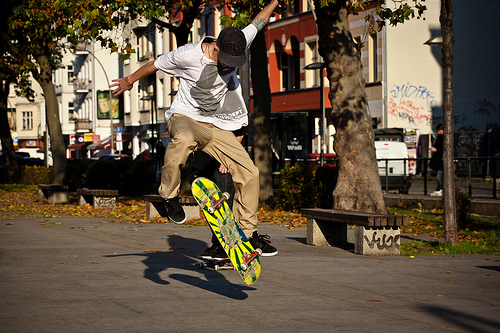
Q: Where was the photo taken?
A: It was taken at the park.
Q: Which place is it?
A: It is a park.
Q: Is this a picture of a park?
A: Yes, it is showing a park.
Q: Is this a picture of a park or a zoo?
A: It is showing a park.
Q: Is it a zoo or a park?
A: It is a park.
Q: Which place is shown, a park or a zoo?
A: It is a park.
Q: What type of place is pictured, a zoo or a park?
A: It is a park.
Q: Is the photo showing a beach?
A: No, the picture is showing a park.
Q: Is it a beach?
A: No, it is a park.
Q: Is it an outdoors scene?
A: Yes, it is outdoors.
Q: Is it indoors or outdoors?
A: It is outdoors.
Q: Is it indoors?
A: No, it is outdoors.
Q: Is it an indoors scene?
A: No, it is outdoors.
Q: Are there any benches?
A: Yes, there is a bench.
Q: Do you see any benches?
A: Yes, there is a bench.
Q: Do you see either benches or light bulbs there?
A: Yes, there is a bench.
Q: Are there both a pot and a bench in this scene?
A: No, there is a bench but no pots.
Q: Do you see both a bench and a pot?
A: No, there is a bench but no pots.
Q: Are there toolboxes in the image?
A: No, there are no toolboxes.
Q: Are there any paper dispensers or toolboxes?
A: No, there are no toolboxes or paper dispensers.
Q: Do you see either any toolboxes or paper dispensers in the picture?
A: No, there are no toolboxes or paper dispensers.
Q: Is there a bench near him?
A: Yes, there is a bench near the boy.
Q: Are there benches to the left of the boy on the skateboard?
A: Yes, there is a bench to the left of the boy.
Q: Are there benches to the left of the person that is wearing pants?
A: Yes, there is a bench to the left of the boy.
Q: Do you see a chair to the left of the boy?
A: No, there is a bench to the left of the boy.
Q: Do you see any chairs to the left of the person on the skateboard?
A: No, there is a bench to the left of the boy.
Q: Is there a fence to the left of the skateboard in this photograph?
A: No, there is a bench to the left of the skateboard.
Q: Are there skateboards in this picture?
A: Yes, there is a skateboard.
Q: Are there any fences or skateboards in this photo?
A: Yes, there is a skateboard.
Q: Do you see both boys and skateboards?
A: Yes, there are both a skateboard and a boy.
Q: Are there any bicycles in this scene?
A: No, there are no bicycles.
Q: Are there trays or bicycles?
A: No, there are no bicycles or trays.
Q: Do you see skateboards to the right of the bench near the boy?
A: Yes, there is a skateboard to the right of the bench.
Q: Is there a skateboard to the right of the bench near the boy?
A: Yes, there is a skateboard to the right of the bench.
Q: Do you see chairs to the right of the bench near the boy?
A: No, there is a skateboard to the right of the bench.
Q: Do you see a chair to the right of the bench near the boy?
A: No, there is a skateboard to the right of the bench.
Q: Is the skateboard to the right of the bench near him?
A: Yes, the skateboard is to the right of the bench.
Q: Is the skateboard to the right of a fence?
A: No, the skateboard is to the right of the bench.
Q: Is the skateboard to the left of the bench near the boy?
A: No, the skateboard is to the right of the bench.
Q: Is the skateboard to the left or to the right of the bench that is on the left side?
A: The skateboard is to the right of the bench.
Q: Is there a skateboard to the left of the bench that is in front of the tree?
A: Yes, there is a skateboard to the left of the bench.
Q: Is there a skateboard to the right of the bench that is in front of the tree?
A: No, the skateboard is to the left of the bench.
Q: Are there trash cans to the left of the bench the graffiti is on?
A: No, there is a skateboard to the left of the bench.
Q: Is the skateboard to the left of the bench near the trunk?
A: Yes, the skateboard is to the left of the bench.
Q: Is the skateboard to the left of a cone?
A: No, the skateboard is to the left of the bench.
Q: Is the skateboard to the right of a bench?
A: No, the skateboard is to the left of a bench.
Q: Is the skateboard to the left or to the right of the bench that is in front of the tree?
A: The skateboard is to the left of the bench.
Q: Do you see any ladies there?
A: No, there are no ladies.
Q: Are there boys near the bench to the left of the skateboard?
A: Yes, there is a boy near the bench.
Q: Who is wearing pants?
A: The boy is wearing pants.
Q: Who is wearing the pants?
A: The boy is wearing pants.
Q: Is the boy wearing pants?
A: Yes, the boy is wearing pants.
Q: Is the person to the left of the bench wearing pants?
A: Yes, the boy is wearing pants.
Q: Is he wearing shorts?
A: No, the boy is wearing pants.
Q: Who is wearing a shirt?
A: The boy is wearing a shirt.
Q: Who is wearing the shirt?
A: The boy is wearing a shirt.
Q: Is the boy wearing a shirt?
A: Yes, the boy is wearing a shirt.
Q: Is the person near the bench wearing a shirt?
A: Yes, the boy is wearing a shirt.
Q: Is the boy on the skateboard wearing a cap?
A: No, the boy is wearing a shirt.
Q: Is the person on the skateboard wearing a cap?
A: No, the boy is wearing a shirt.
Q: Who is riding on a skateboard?
A: The boy is riding on a skateboard.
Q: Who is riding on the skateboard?
A: The boy is riding on a skateboard.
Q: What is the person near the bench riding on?
A: The boy is riding on a skateboard.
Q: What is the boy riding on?
A: The boy is riding on a skateboard.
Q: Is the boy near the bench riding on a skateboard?
A: Yes, the boy is riding on a skateboard.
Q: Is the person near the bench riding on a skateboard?
A: Yes, the boy is riding on a skateboard.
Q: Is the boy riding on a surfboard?
A: No, the boy is riding on a skateboard.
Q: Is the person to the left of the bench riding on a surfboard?
A: No, the boy is riding on a skateboard.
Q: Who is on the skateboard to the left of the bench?
A: The boy is on the skateboard.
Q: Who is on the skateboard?
A: The boy is on the skateboard.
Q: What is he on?
A: The boy is on the skateboard.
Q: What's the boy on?
A: The boy is on the skateboard.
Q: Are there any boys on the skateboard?
A: Yes, there is a boy on the skateboard.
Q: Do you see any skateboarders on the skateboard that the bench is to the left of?
A: No, there is a boy on the skateboard.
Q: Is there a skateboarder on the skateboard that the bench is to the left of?
A: No, there is a boy on the skateboard.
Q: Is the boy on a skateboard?
A: Yes, the boy is on a skateboard.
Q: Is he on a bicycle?
A: No, the boy is on a skateboard.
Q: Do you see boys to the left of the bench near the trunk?
A: Yes, there is a boy to the left of the bench.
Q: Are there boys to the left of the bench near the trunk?
A: Yes, there is a boy to the left of the bench.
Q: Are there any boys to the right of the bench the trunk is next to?
A: No, the boy is to the left of the bench.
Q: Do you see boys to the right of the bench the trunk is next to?
A: No, the boy is to the left of the bench.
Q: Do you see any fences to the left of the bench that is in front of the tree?
A: No, there is a boy to the left of the bench.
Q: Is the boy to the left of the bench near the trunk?
A: Yes, the boy is to the left of the bench.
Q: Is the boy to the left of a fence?
A: No, the boy is to the left of the bench.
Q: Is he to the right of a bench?
A: No, the boy is to the left of a bench.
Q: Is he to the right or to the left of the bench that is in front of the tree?
A: The boy is to the left of the bench.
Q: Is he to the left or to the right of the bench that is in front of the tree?
A: The boy is to the left of the bench.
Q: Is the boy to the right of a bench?
A: Yes, the boy is to the right of a bench.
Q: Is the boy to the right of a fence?
A: No, the boy is to the right of a bench.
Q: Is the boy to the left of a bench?
A: No, the boy is to the right of a bench.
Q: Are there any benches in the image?
A: Yes, there is a bench.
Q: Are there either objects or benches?
A: Yes, there is a bench.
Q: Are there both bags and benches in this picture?
A: No, there is a bench but no bags.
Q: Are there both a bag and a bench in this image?
A: No, there is a bench but no bags.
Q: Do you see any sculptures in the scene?
A: No, there are no sculptures.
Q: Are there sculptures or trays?
A: No, there are no sculptures or trays.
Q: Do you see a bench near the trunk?
A: Yes, there is a bench near the trunk.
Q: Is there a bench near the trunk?
A: Yes, there is a bench near the trunk.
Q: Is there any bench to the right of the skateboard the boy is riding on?
A: Yes, there is a bench to the right of the skateboard.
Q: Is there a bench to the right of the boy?
A: Yes, there is a bench to the right of the boy.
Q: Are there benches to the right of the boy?
A: Yes, there is a bench to the right of the boy.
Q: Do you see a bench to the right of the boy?
A: Yes, there is a bench to the right of the boy.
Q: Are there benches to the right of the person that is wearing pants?
A: Yes, there is a bench to the right of the boy.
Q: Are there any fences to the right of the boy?
A: No, there is a bench to the right of the boy.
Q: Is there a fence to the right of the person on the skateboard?
A: No, there is a bench to the right of the boy.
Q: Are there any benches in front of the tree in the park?
A: Yes, there is a bench in front of the tree.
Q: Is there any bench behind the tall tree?
A: No, the bench is in front of the tree.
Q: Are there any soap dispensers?
A: No, there are no soap dispensers.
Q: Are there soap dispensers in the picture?
A: No, there are no soap dispensers.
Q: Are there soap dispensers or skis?
A: No, there are no soap dispensers or skis.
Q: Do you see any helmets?
A: No, there are no helmets.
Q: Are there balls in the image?
A: No, there are no balls.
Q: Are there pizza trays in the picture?
A: No, there are no pizza trays.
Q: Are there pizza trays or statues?
A: No, there are no pizza trays or statues.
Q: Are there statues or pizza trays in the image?
A: No, there are no pizza trays or statues.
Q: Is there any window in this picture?
A: Yes, there is a window.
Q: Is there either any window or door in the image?
A: Yes, there is a window.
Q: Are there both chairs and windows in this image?
A: No, there is a window but no chairs.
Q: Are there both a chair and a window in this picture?
A: No, there is a window but no chairs.